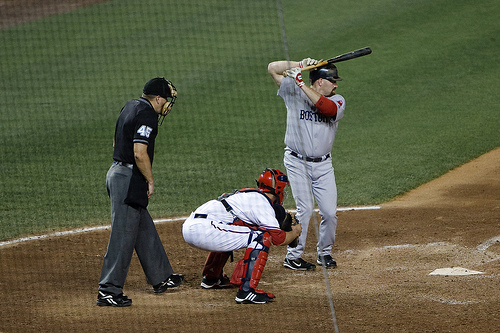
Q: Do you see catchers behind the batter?
A: Yes, there is a catcher behind the batter.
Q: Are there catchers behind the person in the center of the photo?
A: Yes, there is a catcher behind the batter.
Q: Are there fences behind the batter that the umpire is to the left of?
A: No, there is a catcher behind the batter.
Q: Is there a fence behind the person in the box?
A: No, there is a catcher behind the batter.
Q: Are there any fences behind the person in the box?
A: No, there is a catcher behind the batter.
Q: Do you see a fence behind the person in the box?
A: No, there is a catcher behind the batter.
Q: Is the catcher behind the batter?
A: Yes, the catcher is behind the batter.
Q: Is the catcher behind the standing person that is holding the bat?
A: Yes, the catcher is behind the batter.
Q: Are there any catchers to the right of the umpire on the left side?
A: Yes, there is a catcher to the right of the umpire.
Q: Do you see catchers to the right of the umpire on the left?
A: Yes, there is a catcher to the right of the umpire.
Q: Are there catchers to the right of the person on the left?
A: Yes, there is a catcher to the right of the umpire.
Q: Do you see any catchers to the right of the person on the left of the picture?
A: Yes, there is a catcher to the right of the umpire.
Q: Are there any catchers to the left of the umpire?
A: No, the catcher is to the right of the umpire.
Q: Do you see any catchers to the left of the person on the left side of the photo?
A: No, the catcher is to the right of the umpire.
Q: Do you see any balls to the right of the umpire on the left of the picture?
A: No, there is a catcher to the right of the umpire.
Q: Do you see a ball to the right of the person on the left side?
A: No, there is a catcher to the right of the umpire.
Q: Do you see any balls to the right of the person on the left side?
A: No, there is a catcher to the right of the umpire.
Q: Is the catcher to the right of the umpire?
A: Yes, the catcher is to the right of the umpire.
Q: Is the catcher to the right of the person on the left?
A: Yes, the catcher is to the right of the umpire.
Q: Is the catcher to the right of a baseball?
A: No, the catcher is to the right of the umpire.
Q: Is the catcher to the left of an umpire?
A: No, the catcher is to the right of an umpire.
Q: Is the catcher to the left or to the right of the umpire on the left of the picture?
A: The catcher is to the right of the umpire.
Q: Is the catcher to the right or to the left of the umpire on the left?
A: The catcher is to the right of the umpire.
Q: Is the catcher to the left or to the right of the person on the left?
A: The catcher is to the right of the umpire.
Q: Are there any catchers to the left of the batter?
A: Yes, there is a catcher to the left of the batter.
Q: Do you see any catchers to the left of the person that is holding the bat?
A: Yes, there is a catcher to the left of the batter.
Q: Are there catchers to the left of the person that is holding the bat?
A: Yes, there is a catcher to the left of the batter.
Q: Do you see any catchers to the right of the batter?
A: No, the catcher is to the left of the batter.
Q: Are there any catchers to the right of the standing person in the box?
A: No, the catcher is to the left of the batter.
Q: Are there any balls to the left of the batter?
A: No, there is a catcher to the left of the batter.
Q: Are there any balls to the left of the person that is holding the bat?
A: No, there is a catcher to the left of the batter.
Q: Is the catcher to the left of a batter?
A: Yes, the catcher is to the left of a batter.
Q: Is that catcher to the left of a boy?
A: No, the catcher is to the left of a batter.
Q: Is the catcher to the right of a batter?
A: No, the catcher is to the left of a batter.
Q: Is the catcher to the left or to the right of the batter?
A: The catcher is to the left of the batter.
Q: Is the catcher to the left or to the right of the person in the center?
A: The catcher is to the left of the batter.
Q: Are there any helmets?
A: Yes, there is a helmet.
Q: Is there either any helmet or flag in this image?
A: Yes, there is a helmet.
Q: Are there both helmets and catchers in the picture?
A: Yes, there are both a helmet and a catcher.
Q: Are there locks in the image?
A: No, there are no locks.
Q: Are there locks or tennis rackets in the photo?
A: No, there are no locks or tennis rackets.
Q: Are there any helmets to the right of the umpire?
A: Yes, there is a helmet to the right of the umpire.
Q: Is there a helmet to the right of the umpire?
A: Yes, there is a helmet to the right of the umpire.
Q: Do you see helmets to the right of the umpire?
A: Yes, there is a helmet to the right of the umpire.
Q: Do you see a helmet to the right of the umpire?
A: Yes, there is a helmet to the right of the umpire.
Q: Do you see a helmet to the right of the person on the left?
A: Yes, there is a helmet to the right of the umpire.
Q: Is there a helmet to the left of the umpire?
A: No, the helmet is to the right of the umpire.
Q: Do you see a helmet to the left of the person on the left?
A: No, the helmet is to the right of the umpire.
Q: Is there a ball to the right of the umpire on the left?
A: No, there is a helmet to the right of the umpire.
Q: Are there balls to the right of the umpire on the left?
A: No, there is a helmet to the right of the umpire.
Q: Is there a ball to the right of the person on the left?
A: No, there is a helmet to the right of the umpire.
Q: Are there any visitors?
A: No, there are no visitors.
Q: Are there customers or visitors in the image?
A: No, there are no visitors or customers.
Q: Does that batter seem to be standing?
A: Yes, the batter is standing.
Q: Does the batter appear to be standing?
A: Yes, the batter is standing.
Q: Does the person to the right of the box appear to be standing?
A: Yes, the batter is standing.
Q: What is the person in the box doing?
A: The batter is standing.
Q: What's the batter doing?
A: The batter is standing.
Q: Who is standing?
A: The batter is standing.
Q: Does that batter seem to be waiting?
A: Yes, the batter is waiting.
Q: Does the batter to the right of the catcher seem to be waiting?
A: Yes, the batter is waiting.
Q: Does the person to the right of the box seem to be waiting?
A: Yes, the batter is waiting.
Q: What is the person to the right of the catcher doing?
A: The batter is waiting.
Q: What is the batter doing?
A: The batter is waiting.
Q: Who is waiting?
A: The batter is waiting.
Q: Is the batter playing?
A: No, the batter is waiting.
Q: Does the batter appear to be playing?
A: No, the batter is waiting.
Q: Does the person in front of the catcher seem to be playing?
A: No, the batter is waiting.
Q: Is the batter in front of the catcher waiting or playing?
A: The batter is waiting.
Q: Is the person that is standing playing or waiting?
A: The batter is waiting.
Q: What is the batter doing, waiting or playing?
A: The batter is waiting.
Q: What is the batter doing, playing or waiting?
A: The batter is waiting.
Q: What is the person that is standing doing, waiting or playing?
A: The batter is waiting.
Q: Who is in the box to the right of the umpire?
A: The batter is in the box.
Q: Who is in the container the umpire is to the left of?
A: The batter is in the box.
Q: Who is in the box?
A: The batter is in the box.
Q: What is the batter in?
A: The batter is in the box.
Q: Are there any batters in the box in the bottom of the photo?
A: Yes, there is a batter in the box.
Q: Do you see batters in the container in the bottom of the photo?
A: Yes, there is a batter in the box.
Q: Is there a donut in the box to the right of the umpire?
A: No, there is a batter in the box.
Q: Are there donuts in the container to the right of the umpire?
A: No, there is a batter in the box.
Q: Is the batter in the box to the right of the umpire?
A: Yes, the batter is in the box.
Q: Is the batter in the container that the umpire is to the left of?
A: Yes, the batter is in the box.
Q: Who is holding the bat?
A: The batter is holding the bat.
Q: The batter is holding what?
A: The batter is holding the bat.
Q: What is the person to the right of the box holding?
A: The batter is holding the bat.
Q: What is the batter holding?
A: The batter is holding the bat.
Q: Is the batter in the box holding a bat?
A: Yes, the batter is holding a bat.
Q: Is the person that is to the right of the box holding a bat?
A: Yes, the batter is holding a bat.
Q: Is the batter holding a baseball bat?
A: No, the batter is holding a bat.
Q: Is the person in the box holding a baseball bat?
A: No, the batter is holding a bat.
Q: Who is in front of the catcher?
A: The batter is in front of the catcher.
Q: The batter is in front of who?
A: The batter is in front of the catcher.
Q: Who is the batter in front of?
A: The batter is in front of the catcher.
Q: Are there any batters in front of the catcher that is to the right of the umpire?
A: Yes, there is a batter in front of the catcher.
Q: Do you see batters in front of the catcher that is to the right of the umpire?
A: Yes, there is a batter in front of the catcher.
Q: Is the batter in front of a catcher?
A: Yes, the batter is in front of a catcher.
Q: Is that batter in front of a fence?
A: No, the batter is in front of a catcher.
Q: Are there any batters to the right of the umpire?
A: Yes, there is a batter to the right of the umpire.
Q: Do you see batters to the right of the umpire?
A: Yes, there is a batter to the right of the umpire.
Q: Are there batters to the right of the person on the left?
A: Yes, there is a batter to the right of the umpire.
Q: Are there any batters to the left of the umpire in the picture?
A: No, the batter is to the right of the umpire.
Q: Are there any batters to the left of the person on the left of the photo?
A: No, the batter is to the right of the umpire.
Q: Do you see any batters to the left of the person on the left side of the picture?
A: No, the batter is to the right of the umpire.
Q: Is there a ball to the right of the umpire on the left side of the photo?
A: No, there is a batter to the right of the umpire.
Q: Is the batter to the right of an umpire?
A: Yes, the batter is to the right of an umpire.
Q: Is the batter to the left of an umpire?
A: No, the batter is to the right of an umpire.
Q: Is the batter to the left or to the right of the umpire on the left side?
A: The batter is to the right of the umpire.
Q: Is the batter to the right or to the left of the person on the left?
A: The batter is to the right of the umpire.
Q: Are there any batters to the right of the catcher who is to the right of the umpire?
A: Yes, there is a batter to the right of the catcher.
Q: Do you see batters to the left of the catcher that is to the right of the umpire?
A: No, the batter is to the right of the catcher.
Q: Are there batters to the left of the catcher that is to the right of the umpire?
A: No, the batter is to the right of the catcher.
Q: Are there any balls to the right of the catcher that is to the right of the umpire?
A: No, there is a batter to the right of the catcher.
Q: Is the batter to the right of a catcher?
A: Yes, the batter is to the right of a catcher.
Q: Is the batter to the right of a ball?
A: No, the batter is to the right of a catcher.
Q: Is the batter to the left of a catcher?
A: No, the batter is to the right of a catcher.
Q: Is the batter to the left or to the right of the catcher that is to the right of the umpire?
A: The batter is to the right of the catcher.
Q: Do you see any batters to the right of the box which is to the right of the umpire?
A: Yes, there is a batter to the right of the box.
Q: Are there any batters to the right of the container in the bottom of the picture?
A: Yes, there is a batter to the right of the box.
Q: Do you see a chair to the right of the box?
A: No, there is a batter to the right of the box.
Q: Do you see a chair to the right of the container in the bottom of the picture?
A: No, there is a batter to the right of the box.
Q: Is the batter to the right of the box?
A: Yes, the batter is to the right of the box.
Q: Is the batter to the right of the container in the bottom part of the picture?
A: Yes, the batter is to the right of the box.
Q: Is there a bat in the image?
A: Yes, there is a bat.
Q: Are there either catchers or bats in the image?
A: Yes, there is a bat.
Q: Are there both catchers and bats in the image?
A: Yes, there are both a bat and a catcher.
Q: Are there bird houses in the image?
A: No, there are no bird houses.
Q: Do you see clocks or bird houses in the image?
A: No, there are no bird houses or clocks.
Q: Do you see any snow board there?
A: No, there are no snowboards.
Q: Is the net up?
A: Yes, the net is up.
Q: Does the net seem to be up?
A: Yes, the net is up.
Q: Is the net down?
A: No, the net is up.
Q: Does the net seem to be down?
A: No, the net is up.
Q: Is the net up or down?
A: The net is up.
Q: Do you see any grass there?
A: Yes, there is grass.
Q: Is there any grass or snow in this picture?
A: Yes, there is grass.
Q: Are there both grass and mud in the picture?
A: No, there is grass but no mud.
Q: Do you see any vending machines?
A: No, there are no vending machines.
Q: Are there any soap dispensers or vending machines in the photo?
A: No, there are no vending machines or soap dispensers.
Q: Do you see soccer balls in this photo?
A: No, there are no soccer balls.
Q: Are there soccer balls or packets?
A: No, there are no soccer balls or packets.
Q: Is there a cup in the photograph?
A: No, there are no cups.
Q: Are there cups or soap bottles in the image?
A: No, there are no cups or soap bottles.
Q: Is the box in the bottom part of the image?
A: Yes, the box is in the bottom of the image.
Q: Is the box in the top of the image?
A: No, the box is in the bottom of the image.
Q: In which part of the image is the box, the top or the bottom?
A: The box is in the bottom of the image.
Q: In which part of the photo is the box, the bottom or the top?
A: The box is in the bottom of the image.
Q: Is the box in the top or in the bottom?
A: The box is in the bottom of the image.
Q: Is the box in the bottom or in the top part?
A: The box is in the bottom of the image.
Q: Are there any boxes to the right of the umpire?
A: Yes, there is a box to the right of the umpire.